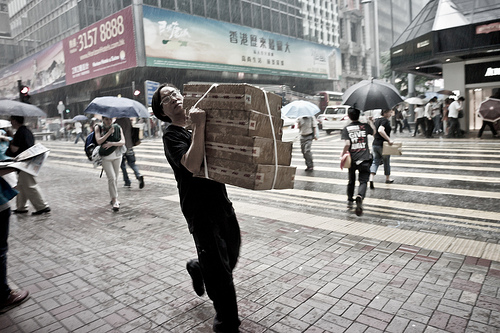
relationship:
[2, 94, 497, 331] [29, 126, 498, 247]
street by road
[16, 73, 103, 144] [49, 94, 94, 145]
sign on pole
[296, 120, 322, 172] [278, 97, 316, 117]
man with umbrella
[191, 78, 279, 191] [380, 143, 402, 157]
string around boxes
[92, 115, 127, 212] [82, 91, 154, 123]
lady with umbrella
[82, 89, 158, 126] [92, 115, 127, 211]
umbrella covering lady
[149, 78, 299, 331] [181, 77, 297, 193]
person carrying boxes